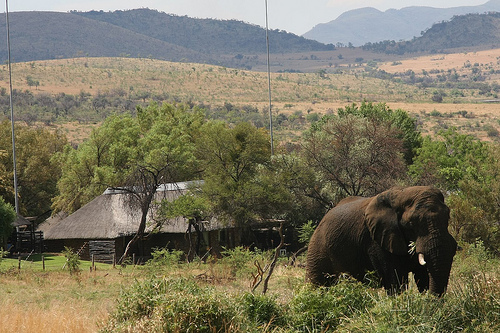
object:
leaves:
[195, 200, 212, 208]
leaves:
[183, 115, 206, 129]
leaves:
[476, 181, 497, 193]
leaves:
[477, 177, 497, 186]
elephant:
[305, 185, 457, 300]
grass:
[1, 252, 127, 332]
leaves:
[460, 202, 476, 217]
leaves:
[134, 120, 144, 128]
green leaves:
[168, 121, 242, 163]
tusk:
[418, 253, 426, 265]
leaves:
[168, 302, 197, 317]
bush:
[158, 291, 233, 331]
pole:
[4, 0, 21, 251]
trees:
[222, 177, 330, 257]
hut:
[34, 179, 285, 265]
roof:
[42, 186, 285, 243]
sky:
[3, 2, 487, 37]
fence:
[0, 252, 150, 271]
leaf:
[228, 129, 238, 144]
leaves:
[407, 165, 417, 174]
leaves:
[96, 166, 117, 183]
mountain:
[399, 12, 498, 52]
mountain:
[67, 8, 334, 54]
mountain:
[0, 10, 256, 67]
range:
[3, 2, 499, 65]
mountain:
[300, 0, 500, 49]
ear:
[364, 190, 404, 253]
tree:
[54, 107, 215, 267]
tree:
[195, 109, 282, 252]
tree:
[253, 152, 334, 252]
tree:
[305, 104, 425, 198]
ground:
[2, 47, 497, 331]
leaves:
[397, 117, 412, 123]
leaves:
[309, 202, 323, 212]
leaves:
[76, 155, 96, 168]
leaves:
[321, 119, 333, 132]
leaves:
[153, 134, 169, 142]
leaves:
[214, 184, 222, 192]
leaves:
[301, 225, 313, 242]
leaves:
[33, 153, 45, 167]